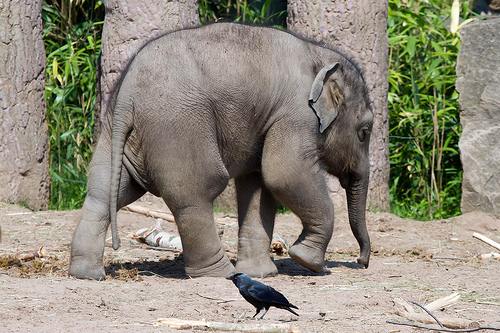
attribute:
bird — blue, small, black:
[228, 273, 299, 321]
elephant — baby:
[70, 23, 372, 276]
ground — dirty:
[2, 202, 498, 331]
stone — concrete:
[136, 228, 182, 252]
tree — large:
[101, 3, 200, 216]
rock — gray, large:
[456, 18, 499, 216]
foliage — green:
[388, 3, 464, 220]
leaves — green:
[43, 3, 103, 211]